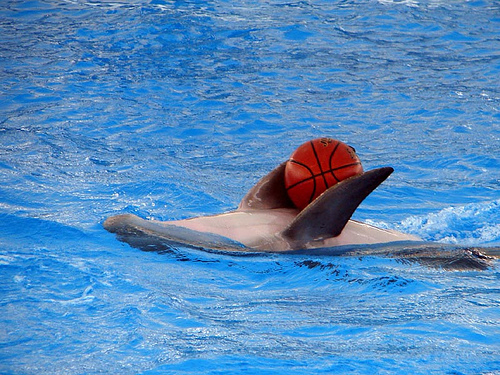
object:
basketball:
[283, 137, 362, 211]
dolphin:
[103, 145, 498, 268]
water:
[1, 1, 102, 176]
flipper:
[274, 165, 394, 239]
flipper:
[239, 159, 302, 210]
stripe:
[283, 160, 362, 191]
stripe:
[308, 137, 330, 191]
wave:
[365, 196, 499, 236]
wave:
[432, 221, 498, 248]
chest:
[159, 208, 299, 253]